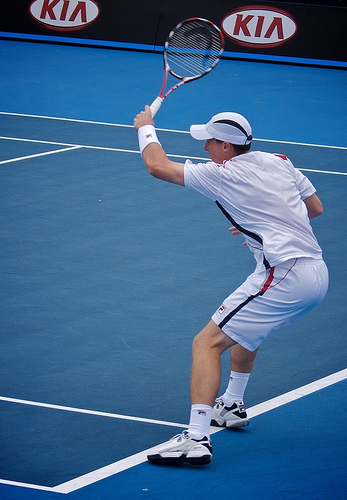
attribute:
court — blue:
[1, 39, 346, 499]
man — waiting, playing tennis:
[134, 107, 329, 465]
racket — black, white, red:
[140, 17, 224, 119]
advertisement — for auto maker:
[219, 5, 297, 50]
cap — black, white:
[189, 112, 253, 146]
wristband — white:
[136, 125, 162, 157]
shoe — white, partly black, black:
[148, 430, 213, 464]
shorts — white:
[212, 258, 329, 353]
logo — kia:
[27, 0, 101, 37]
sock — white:
[189, 403, 210, 441]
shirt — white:
[182, 150, 323, 273]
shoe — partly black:
[212, 397, 247, 428]